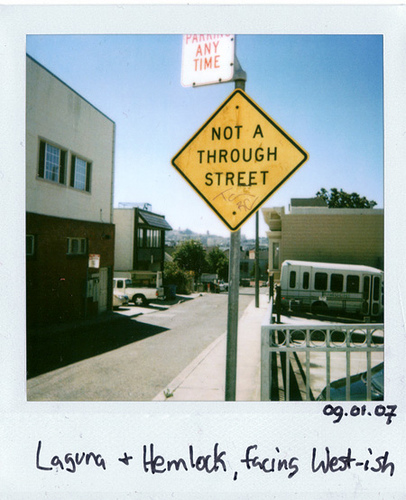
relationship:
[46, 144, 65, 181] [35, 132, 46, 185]
windows with shutters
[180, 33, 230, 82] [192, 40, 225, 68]
sign with letters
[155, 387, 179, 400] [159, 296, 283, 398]
weed growing sidewalk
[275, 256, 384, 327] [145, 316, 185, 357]
bus in a lot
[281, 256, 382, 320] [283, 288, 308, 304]
bus with stripes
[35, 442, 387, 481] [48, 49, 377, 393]
label for the photo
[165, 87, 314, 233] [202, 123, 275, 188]
road signs with information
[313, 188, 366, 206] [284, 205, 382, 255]
tree peeking above building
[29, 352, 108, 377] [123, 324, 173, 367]
shadow on the street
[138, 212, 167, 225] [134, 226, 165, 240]
awning above the windows